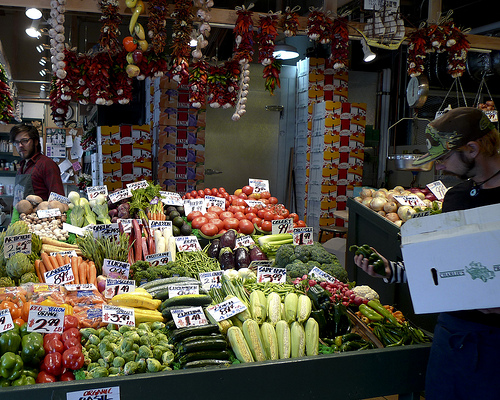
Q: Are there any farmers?
A: No, there are no farmers.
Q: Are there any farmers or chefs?
A: No, there are no farmers or chefs.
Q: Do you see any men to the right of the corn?
A: Yes, there is a man to the right of the corn.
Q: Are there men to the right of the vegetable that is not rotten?
A: Yes, there is a man to the right of the corn.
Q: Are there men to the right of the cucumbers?
A: Yes, there is a man to the right of the cucumbers.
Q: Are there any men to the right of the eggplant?
A: Yes, there is a man to the right of the eggplant.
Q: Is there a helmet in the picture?
A: No, there are no helmets.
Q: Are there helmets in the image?
A: No, there are no helmets.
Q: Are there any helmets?
A: No, there are no helmets.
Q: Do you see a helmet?
A: No, there are no helmets.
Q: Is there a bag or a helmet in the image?
A: No, there are no helmets or bags.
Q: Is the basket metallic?
A: Yes, the basket is metallic.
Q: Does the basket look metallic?
A: Yes, the basket is metallic.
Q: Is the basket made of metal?
A: Yes, the basket is made of metal.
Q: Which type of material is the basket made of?
A: The basket is made of metal.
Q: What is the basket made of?
A: The basket is made of metal.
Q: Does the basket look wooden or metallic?
A: The basket is metallic.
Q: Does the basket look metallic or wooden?
A: The basket is metallic.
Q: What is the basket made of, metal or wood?
A: The basket is made of metal.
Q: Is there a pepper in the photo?
A: Yes, there are peppers.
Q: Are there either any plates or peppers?
A: Yes, there are peppers.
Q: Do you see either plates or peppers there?
A: Yes, there are peppers.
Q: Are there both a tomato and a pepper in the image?
A: Yes, there are both a pepper and a tomato.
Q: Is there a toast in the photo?
A: No, there are no toasts.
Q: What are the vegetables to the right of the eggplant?
A: The vegetables are peppers.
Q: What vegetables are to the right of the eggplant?
A: The vegetables are peppers.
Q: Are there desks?
A: No, there are no desks.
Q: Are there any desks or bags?
A: No, there are no desks or bags.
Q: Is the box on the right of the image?
A: Yes, the box is on the right of the image.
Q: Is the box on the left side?
A: No, the box is on the right of the image.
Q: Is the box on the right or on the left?
A: The box is on the right of the image.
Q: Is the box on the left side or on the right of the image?
A: The box is on the right of the image.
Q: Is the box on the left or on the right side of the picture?
A: The box is on the right of the image.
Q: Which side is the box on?
A: The box is on the right of the image.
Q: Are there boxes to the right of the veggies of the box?
A: Yes, there is a box to the right of the vegetables.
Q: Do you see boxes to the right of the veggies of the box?
A: Yes, there is a box to the right of the vegetables.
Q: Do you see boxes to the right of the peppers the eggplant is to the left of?
A: Yes, there is a box to the right of the peppers.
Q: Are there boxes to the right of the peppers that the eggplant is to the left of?
A: Yes, there is a box to the right of the peppers.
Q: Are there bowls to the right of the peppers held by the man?
A: No, there is a box to the right of the peppers.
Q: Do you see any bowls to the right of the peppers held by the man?
A: No, there is a box to the right of the peppers.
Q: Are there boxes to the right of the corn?
A: Yes, there is a box to the right of the corn.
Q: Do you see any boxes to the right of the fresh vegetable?
A: Yes, there is a box to the right of the corn.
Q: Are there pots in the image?
A: No, there are no pots.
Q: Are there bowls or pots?
A: No, there are no pots or bowls.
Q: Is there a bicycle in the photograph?
A: No, there are no bicycles.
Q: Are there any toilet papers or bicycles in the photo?
A: No, there are no bicycles or toilet papers.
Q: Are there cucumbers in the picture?
A: Yes, there are cucumbers.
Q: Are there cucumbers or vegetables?
A: Yes, there are cucumbers.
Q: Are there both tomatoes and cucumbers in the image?
A: Yes, there are both cucumbers and tomatoes.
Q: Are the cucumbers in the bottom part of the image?
A: Yes, the cucumbers are in the bottom of the image.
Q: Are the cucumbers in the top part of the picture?
A: No, the cucumbers are in the bottom of the image.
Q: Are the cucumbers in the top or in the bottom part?
A: The cucumbers are in the bottom of the image.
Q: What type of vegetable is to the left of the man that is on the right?
A: The vegetables are cucumbers.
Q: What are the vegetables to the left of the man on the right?
A: The vegetables are cucumbers.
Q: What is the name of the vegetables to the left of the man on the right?
A: The vegetables are cucumbers.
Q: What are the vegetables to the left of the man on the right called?
A: The vegetables are cucumbers.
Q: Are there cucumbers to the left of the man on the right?
A: Yes, there are cucumbers to the left of the man.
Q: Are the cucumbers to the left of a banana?
A: No, the cucumbers are to the left of a man.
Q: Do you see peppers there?
A: Yes, there are peppers.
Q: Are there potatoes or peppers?
A: Yes, there are peppers.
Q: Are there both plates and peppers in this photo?
A: No, there are peppers but no plates.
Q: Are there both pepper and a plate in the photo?
A: No, there are peppers but no plates.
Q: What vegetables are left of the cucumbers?
A: The vegetables are peppers.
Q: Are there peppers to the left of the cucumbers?
A: Yes, there are peppers to the left of the cucumbers.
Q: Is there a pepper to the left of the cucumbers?
A: Yes, there are peppers to the left of the cucumbers.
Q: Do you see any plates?
A: No, there are no plates.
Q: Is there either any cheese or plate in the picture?
A: No, there are no plates or cheese.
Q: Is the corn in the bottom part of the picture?
A: Yes, the corn is in the bottom of the image.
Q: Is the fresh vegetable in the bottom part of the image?
A: Yes, the corn is in the bottom of the image.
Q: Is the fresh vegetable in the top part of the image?
A: No, the corn is in the bottom of the image.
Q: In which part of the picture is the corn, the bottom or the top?
A: The corn is in the bottom of the image.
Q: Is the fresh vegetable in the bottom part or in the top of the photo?
A: The corn is in the bottom of the image.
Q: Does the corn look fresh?
A: Yes, the corn is fresh.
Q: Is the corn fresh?
A: Yes, the corn is fresh.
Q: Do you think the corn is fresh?
A: Yes, the corn is fresh.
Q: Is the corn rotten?
A: No, the corn is fresh.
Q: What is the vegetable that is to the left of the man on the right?
A: The vegetable is corn.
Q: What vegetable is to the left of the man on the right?
A: The vegetable is corn.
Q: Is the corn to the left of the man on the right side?
A: Yes, the corn is to the left of the man.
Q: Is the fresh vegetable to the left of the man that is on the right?
A: Yes, the corn is to the left of the man.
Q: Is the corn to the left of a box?
A: Yes, the corn is to the left of a box.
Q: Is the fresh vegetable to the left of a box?
A: Yes, the corn is to the left of a box.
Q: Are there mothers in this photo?
A: No, there are no mothers.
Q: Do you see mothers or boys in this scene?
A: No, there are no mothers or boys.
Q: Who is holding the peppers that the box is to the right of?
A: The man is holding the peppers.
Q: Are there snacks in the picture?
A: No, there are no snacks.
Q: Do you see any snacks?
A: No, there are no snacks.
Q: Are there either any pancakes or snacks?
A: No, there are no snacks or pancakes.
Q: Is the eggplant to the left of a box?
A: Yes, the eggplant is to the left of a box.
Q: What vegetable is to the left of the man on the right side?
A: The vegetable is an eggplant.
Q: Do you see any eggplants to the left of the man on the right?
A: Yes, there is an eggplant to the left of the man.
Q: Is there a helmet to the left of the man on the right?
A: No, there is an eggplant to the left of the man.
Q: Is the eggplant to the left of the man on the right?
A: Yes, the eggplant is to the left of the man.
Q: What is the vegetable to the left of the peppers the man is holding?
A: The vegetable is an eggplant.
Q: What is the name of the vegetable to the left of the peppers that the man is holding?
A: The vegetable is an eggplant.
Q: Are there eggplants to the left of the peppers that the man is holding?
A: Yes, there is an eggplant to the left of the peppers.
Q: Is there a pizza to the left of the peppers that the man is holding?
A: No, there is an eggplant to the left of the peppers.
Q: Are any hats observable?
A: Yes, there is a hat.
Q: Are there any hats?
A: Yes, there is a hat.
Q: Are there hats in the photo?
A: Yes, there is a hat.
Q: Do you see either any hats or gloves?
A: Yes, there is a hat.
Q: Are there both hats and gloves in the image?
A: No, there is a hat but no gloves.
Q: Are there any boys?
A: No, there are no boys.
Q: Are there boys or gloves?
A: No, there are no boys or gloves.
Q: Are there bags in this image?
A: No, there are no bags.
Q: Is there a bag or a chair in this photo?
A: No, there are no bags or chairs.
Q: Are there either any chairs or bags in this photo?
A: No, there are no bags or chairs.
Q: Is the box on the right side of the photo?
A: Yes, the box is on the right of the image.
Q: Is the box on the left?
A: No, the box is on the right of the image.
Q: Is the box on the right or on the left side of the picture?
A: The box is on the right of the image.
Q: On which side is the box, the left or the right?
A: The box is on the right of the image.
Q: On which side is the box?
A: The box is on the right of the image.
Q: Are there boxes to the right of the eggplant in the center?
A: Yes, there is a box to the right of the eggplant.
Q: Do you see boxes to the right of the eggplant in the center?
A: Yes, there is a box to the right of the eggplant.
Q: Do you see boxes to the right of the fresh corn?
A: Yes, there is a box to the right of the corn.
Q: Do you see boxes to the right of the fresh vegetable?
A: Yes, there is a box to the right of the corn.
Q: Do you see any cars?
A: No, there are no cars.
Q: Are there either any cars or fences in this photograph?
A: No, there are no cars or fences.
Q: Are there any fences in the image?
A: No, there are no fences.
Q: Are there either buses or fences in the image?
A: No, there are no fences or buses.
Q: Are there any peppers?
A: Yes, there are peppers.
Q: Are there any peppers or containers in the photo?
A: Yes, there are peppers.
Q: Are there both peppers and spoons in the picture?
A: No, there are peppers but no spoons.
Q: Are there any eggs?
A: No, there are no eggs.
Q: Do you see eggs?
A: No, there are no eggs.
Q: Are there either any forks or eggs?
A: No, there are no eggs or forks.